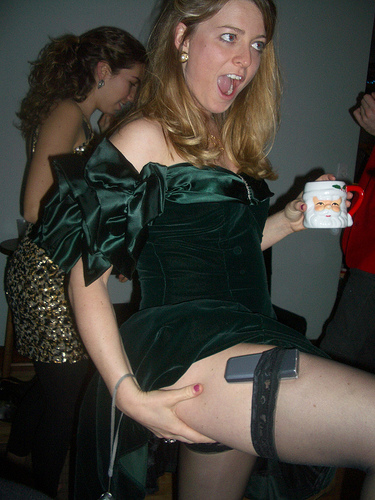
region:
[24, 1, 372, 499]
A horny looking white woman.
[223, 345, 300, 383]
A telephone strapped to a pantyhose.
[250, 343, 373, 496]
A green pantyhose in the woman's leg.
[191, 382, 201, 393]
A pink nail polish on the woman's thumb.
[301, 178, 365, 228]
A mug with a sculpture of Santa Claus's head.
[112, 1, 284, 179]
The face of a happy white woman.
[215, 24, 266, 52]
The beautiful eyes a pretty blonde woman.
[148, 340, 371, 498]
The voluptuous legs of a beautiful white girl.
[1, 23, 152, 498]
A beautiful girl in the background.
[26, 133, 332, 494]
A nice green dress worn for a special occasion.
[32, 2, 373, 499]
Woman raise right leg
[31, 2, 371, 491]
Woman has a green dress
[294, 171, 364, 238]
White cup of Santa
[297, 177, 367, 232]
Cup has a red handle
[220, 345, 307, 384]
Cell phone on leg of woman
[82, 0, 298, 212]
Woman is blonde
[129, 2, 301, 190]
Woman open her mouth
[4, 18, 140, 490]
Woman wears a shiny dress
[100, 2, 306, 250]
Hair is free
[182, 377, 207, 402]
Thump has manicure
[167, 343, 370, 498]
the woman has on thigh highs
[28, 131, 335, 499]
the woman is wearing a dress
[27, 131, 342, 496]
the dress is green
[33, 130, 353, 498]
the dress is velvet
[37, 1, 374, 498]
the woman needs to go home because she's drunk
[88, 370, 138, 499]
the woman has a strap around her arm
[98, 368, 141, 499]
the strap is grey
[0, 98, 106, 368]
the woman is wearing a sequin dress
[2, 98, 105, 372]
the dress is gold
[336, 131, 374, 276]
the man is wearing a red sweatshirt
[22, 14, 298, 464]
Picture is taken indoors.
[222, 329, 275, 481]
The girl is wearing a garter.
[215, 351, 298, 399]
The woman has a phone in her garter.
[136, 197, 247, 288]
The woman is wearing a dress.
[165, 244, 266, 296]
The woman is wearing a green dress.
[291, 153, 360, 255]
The woman is holding a mug.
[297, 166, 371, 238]
The mug shape is of Santa Clause.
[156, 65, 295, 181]
The woman has long hair.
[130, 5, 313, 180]
The woman's hair is blonde.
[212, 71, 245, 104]
The woman's mouth is open.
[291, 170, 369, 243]
santa claus coffee mug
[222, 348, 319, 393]
black cellular phone in a garter strap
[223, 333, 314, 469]
black garter band around a girl's white leg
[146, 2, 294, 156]
blonde girl with gold earrings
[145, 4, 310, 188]
blonde girl with open mouth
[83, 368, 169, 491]
grey camera strap on a girl's arm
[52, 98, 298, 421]
green velvet and satin off the shoulder dress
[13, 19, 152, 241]
smiling girl with curly blonde hair in a pony tail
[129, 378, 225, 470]
white girl's hand with pink nails and a ring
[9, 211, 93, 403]
gold lame mini skirt